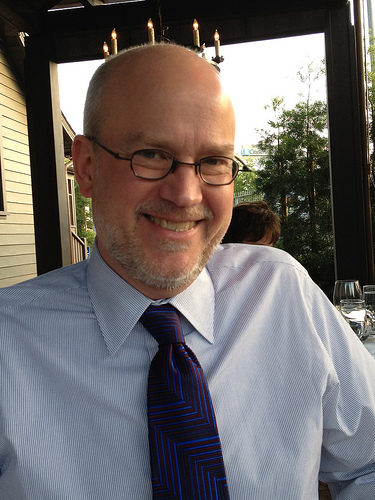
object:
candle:
[148, 14, 155, 43]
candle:
[111, 28, 118, 56]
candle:
[192, 19, 200, 48]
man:
[11, 39, 371, 500]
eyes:
[131, 149, 225, 167]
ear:
[72, 134, 94, 198]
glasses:
[90, 138, 239, 186]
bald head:
[92, 46, 234, 117]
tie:
[138, 308, 232, 500]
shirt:
[0, 248, 374, 499]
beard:
[84, 175, 238, 287]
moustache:
[138, 205, 208, 223]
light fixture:
[88, 8, 229, 75]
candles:
[103, 18, 220, 61]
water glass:
[332, 275, 362, 319]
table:
[357, 329, 375, 360]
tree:
[260, 98, 331, 296]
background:
[52, 29, 338, 307]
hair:
[84, 60, 108, 141]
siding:
[0, 65, 41, 288]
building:
[4, 3, 105, 290]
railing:
[66, 230, 95, 266]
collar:
[87, 237, 219, 353]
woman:
[225, 195, 279, 256]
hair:
[222, 201, 280, 243]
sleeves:
[327, 342, 374, 500]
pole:
[325, 27, 374, 292]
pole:
[28, 62, 71, 272]